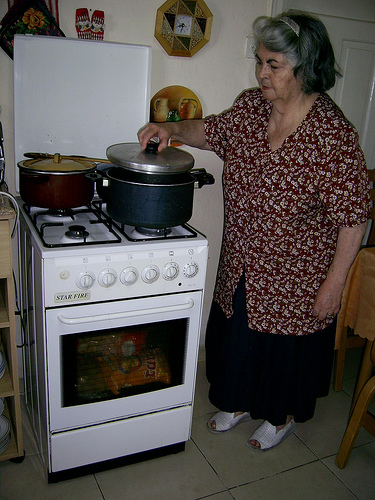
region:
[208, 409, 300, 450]
the sandals are white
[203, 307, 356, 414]
the skirt is black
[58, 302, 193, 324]
the handle on the oven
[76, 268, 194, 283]
the knobs on the stove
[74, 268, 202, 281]
the knobs are white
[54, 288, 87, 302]
the logo is silver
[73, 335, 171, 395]
goods in the oven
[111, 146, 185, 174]
the lid is silver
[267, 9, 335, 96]
the hair is gray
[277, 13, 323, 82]
headband in the hair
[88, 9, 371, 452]
a woman putting a lid on a pan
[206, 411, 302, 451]
a woman's white shoes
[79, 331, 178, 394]
snacks inside of an oven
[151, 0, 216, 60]
a festive looking wall clock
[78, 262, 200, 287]
a row of knobs on an oven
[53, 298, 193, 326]
an oven door handle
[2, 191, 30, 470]
a wooden kitchen rack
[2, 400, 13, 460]
plates on a kitchen rack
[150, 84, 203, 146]
a decorative plate on the wall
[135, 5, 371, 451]
adult female standing near kitchen stove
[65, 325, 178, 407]
bags of chips inside kitchen oven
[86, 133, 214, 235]
large black pot with silver lid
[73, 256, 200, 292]
row of white knobs on stove front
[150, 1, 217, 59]
octagonal clock on wall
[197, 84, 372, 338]
red and white patterned blouse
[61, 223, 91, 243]
gas burner on stove top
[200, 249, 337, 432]
long black ladies skirt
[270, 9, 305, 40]
silver headband on lady's head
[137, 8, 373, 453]
woman cooking in the kitchen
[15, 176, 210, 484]
a small white oven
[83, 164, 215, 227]
a large black pot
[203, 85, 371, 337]
red dress on the woman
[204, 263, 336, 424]
black dress on the woman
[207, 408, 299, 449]
white shoes on the woman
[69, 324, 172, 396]
food being stored in the oven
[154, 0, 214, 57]
a small wooden clock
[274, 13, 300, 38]
a band in the woman's hair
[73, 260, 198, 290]
controls on the oven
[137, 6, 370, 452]
the old woman is standing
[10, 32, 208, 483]
the old fashioned white stove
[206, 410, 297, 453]
the pair of white shoes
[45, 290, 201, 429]
the white oven door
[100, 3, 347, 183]
A woman holding a pot lid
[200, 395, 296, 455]
A pair of white shoes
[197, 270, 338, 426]
A long dark blue skirt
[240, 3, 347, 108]
A woman has gray hair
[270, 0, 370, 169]
A closed white door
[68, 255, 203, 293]
Six white knobs of a stove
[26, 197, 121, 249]
A burner on the stove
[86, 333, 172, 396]
A bag of potato chips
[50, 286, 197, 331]
White handle of an oven door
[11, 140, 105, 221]
Red pot with a lid on top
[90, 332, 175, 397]
A yellow bag of potato chips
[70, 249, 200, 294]
White knobs on a stove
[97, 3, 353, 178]
An elderly woman holding a pot lid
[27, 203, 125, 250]
A burner on a stove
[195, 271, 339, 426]
A long dark skirt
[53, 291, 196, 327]
White handle on an oven door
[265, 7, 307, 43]
Headband in woman's hair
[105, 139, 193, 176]
A silver lid a woman is holding.